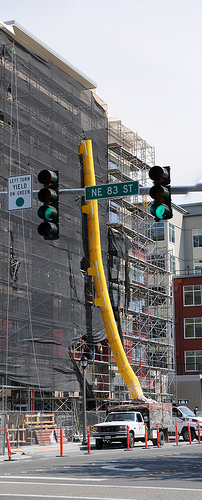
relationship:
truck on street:
[90, 399, 173, 449] [3, 439, 200, 499]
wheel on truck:
[122, 425, 141, 452] [90, 399, 173, 449]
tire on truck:
[153, 425, 174, 448] [90, 399, 173, 449]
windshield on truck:
[102, 409, 147, 427] [90, 399, 173, 449]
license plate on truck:
[96, 431, 121, 445] [90, 399, 173, 449]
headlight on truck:
[112, 421, 135, 439] [90, 399, 173, 449]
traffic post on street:
[51, 425, 71, 463] [3, 439, 200, 499]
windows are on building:
[176, 282, 201, 377] [138, 203, 201, 376]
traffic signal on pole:
[36, 164, 65, 243] [0, 176, 201, 204]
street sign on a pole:
[78, 182, 146, 206] [0, 176, 201, 204]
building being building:
[1, 24, 187, 425] [0, 18, 109, 426]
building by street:
[1, 24, 187, 425] [3, 439, 200, 499]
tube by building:
[75, 131, 180, 404] [1, 24, 187, 425]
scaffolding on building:
[110, 119, 181, 394] [1, 24, 187, 425]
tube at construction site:
[75, 131, 180, 404] [3, 1, 201, 498]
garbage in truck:
[123, 386, 170, 407] [90, 399, 173, 449]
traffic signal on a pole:
[36, 164, 65, 243] [0, 176, 201, 204]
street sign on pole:
[78, 182, 146, 206] [0, 176, 201, 204]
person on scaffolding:
[0, 72, 23, 113] [108, 117, 178, 407]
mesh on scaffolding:
[1, 36, 130, 383] [108, 117, 178, 407]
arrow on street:
[97, 449, 161, 476] [3, 439, 200, 499]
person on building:
[0, 72, 23, 113] [1, 24, 187, 425]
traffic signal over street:
[36, 164, 65, 243] [3, 439, 200, 499]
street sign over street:
[78, 182, 146, 206] [3, 439, 200, 499]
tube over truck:
[75, 131, 180, 404] [90, 399, 173, 449]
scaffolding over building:
[108, 117, 178, 407] [1, 24, 187, 425]